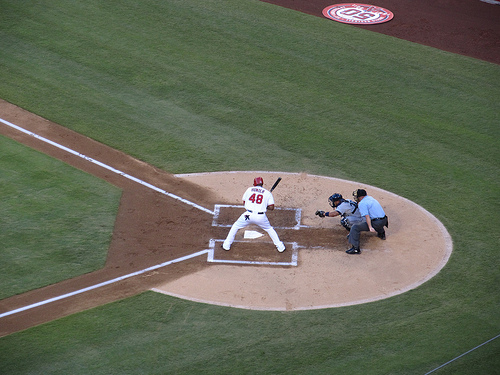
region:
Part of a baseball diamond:
[6, 94, 223, 321]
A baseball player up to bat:
[221, 175, 288, 254]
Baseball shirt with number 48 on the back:
[239, 187, 274, 212]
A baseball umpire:
[352, 187, 387, 241]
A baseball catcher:
[312, 193, 356, 226]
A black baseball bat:
[270, 175, 282, 192]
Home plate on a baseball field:
[242, 227, 263, 240]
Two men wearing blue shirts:
[328, 188, 388, 220]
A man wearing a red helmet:
[249, 175, 265, 188]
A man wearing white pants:
[224, 210, 286, 254]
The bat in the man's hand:
[267, 174, 284, 194]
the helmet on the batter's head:
[247, 174, 267, 187]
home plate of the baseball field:
[240, 226, 265, 242]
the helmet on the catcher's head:
[323, 191, 345, 206]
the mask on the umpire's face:
[350, 183, 365, 203]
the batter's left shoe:
[218, 235, 232, 253]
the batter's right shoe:
[274, 242, 286, 254]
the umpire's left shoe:
[344, 243, 361, 255]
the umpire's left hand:
[366, 223, 378, 235]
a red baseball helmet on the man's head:
[250, 175, 267, 187]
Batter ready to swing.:
[216, 168, 294, 259]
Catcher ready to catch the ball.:
[311, 192, 366, 239]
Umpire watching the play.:
[342, 185, 393, 256]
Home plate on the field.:
[243, 225, 266, 241]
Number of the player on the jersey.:
[244, 187, 264, 209]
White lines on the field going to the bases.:
[3, 115, 235, 317]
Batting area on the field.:
[196, 191, 305, 273]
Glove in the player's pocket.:
[240, 215, 253, 222]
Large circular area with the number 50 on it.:
[318, 3, 395, 27]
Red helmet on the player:
[246, 175, 267, 187]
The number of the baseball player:
[249, 192, 265, 205]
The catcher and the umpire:
[312, 185, 389, 252]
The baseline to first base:
[61, 137, 168, 197]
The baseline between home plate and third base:
[24, 252, 192, 286]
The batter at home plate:
[223, 176, 288, 252]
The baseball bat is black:
[271, 173, 283, 190]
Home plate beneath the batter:
[244, 228, 264, 240]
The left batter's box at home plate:
[208, 242, 296, 262]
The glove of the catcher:
[312, 208, 328, 220]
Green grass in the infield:
[30, 176, 90, 256]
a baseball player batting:
[222, 170, 287, 264]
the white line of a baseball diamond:
[34, 270, 121, 305]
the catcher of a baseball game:
[314, 187, 362, 222]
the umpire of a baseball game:
[353, 186, 390, 232]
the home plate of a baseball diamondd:
[241, 227, 272, 243]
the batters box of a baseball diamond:
[208, 237, 303, 271]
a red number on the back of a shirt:
[244, 192, 269, 206]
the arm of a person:
[313, 206, 345, 220]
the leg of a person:
[265, 222, 282, 248]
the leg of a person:
[346, 220, 366, 247]